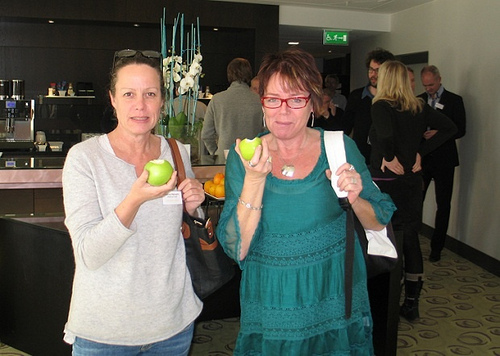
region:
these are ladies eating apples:
[63, 54, 382, 354]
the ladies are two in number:
[63, 46, 368, 354]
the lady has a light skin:
[123, 135, 145, 147]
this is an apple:
[152, 162, 162, 173]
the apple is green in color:
[154, 167, 165, 174]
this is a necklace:
[278, 156, 300, 175]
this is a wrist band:
[247, 203, 259, 210]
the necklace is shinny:
[283, 165, 290, 173]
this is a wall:
[469, 20, 489, 165]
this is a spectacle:
[116, 47, 163, 59]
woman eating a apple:
[60, 32, 215, 349]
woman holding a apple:
[218, 36, 392, 348]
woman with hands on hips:
[370, 52, 439, 324]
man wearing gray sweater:
[202, 45, 259, 151]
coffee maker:
[1, 75, 39, 152]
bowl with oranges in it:
[201, 165, 231, 210]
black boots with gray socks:
[400, 265, 436, 331]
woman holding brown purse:
[66, 31, 226, 344]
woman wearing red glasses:
[216, 41, 377, 349]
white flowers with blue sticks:
[157, 9, 209, 161]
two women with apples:
[78, 48, 337, 354]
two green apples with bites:
[140, 132, 262, 194]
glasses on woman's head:
[115, 40, 166, 77]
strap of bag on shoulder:
[320, 125, 379, 227]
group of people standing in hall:
[351, 49, 468, 269]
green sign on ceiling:
[311, 25, 353, 52]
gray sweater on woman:
[58, 131, 205, 339]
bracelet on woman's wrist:
[235, 193, 267, 214]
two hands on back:
[372, 146, 434, 185]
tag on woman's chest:
[155, 185, 185, 215]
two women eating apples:
[74, 37, 395, 317]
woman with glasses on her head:
[91, 41, 176, 148]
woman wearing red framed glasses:
[251, 76, 313, 122]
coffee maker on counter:
[1, 68, 51, 166]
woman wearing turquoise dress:
[209, 131, 411, 354]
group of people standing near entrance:
[346, 42, 465, 263]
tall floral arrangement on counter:
[147, 8, 204, 150]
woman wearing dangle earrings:
[249, 99, 334, 130]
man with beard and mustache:
[353, 43, 383, 95]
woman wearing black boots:
[391, 262, 435, 342]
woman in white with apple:
[55, 32, 220, 352]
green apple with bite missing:
[131, 150, 176, 190]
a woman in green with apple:
[211, 51, 407, 352]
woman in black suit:
[362, 55, 427, 321]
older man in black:
[405, 55, 470, 266]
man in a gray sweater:
[195, 50, 266, 170]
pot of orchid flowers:
[150, 45, 205, 150]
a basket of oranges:
[195, 160, 235, 200]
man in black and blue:
[345, 45, 390, 140]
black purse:
[161, 137, 246, 309]